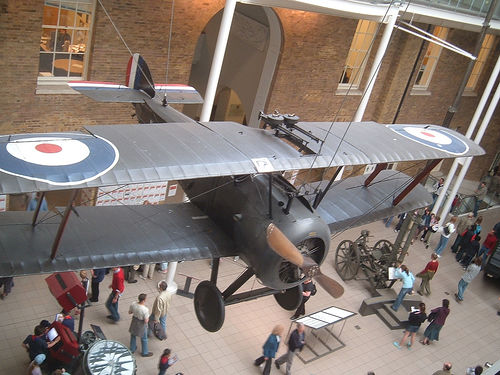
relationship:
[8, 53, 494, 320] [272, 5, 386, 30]
airplane suspended from ceiling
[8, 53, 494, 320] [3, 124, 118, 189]
airplane has blue cicles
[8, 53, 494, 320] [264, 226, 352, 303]
airplane has propellor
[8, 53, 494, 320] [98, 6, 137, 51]
airplane has wires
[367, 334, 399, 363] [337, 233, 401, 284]
floor has a cannon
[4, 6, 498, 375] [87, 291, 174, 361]
museum has people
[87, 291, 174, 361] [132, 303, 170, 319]
people wearing tan shirts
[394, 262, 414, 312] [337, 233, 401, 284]
woman looking at cannon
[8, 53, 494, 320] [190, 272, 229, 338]
airplane has black wheels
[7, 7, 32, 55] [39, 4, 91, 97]
walls have windows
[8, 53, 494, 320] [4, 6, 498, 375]
airplane hung in museum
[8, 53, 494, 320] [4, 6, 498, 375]
airplane hanging in museum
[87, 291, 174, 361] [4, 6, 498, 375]
people at museum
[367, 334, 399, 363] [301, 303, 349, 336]
floor has a sign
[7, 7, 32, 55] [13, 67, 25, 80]
walls made of bricks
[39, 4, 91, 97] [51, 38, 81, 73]
windows have an office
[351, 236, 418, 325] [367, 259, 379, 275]
obstacle made of metal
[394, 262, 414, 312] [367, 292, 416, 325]
woman on a podium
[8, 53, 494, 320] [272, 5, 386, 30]
airplane hanging from ceiling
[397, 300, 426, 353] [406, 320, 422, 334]
woman wearing a skirt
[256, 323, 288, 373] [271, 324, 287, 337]
woman with blonde hair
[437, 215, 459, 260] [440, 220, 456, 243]
woman wearing a white shirt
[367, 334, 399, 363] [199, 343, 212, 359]
floor made of tile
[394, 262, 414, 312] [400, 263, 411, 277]
woman with brown hair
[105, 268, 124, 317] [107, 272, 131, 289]
person with red shirt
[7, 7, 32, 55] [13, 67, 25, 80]
walls are made of bricks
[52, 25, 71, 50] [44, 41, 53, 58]
person in a desk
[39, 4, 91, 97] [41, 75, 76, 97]
windows have white trim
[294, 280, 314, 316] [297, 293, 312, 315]
person has black pants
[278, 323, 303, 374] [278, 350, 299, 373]
person wearing kakki pants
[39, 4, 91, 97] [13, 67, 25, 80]
windows on bricks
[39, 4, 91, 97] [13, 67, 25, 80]
windows on a bricks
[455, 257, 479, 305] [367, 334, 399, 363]
person walking on floor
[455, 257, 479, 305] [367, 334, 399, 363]
person waking on floor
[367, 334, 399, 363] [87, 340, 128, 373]
floor has panels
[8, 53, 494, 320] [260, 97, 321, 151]
airplane has guns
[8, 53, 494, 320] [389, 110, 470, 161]
airplane has target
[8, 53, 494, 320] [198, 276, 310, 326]
airplane has wheels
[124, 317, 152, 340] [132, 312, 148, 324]
jacket on waist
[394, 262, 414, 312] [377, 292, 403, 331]
woman standing on a platform